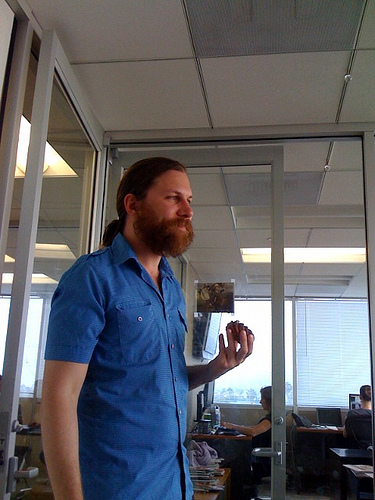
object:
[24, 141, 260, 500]
man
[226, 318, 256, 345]
doughnut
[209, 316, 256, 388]
hand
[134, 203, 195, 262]
bead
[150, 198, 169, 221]
cheeks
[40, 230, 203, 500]
shirt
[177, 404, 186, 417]
buttons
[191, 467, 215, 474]
magazines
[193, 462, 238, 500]
table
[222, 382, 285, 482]
woman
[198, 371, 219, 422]
computer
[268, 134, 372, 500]
screen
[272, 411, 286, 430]
lock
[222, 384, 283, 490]
women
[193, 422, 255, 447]
at desk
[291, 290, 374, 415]
blinds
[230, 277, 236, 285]
taped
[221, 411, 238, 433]
typing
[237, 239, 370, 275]
lights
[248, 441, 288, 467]
handle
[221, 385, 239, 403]
trees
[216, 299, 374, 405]
window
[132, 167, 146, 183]
hair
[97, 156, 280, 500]
newly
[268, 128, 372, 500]
door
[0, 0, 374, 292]
ceiling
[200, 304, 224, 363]
tv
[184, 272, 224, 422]
wall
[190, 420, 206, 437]
pinecone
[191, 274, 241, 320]
image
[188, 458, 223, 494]
pile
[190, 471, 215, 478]
papers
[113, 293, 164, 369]
pocket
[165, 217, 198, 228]
mustache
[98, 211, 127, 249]
ponytail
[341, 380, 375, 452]
office worker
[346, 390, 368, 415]
computer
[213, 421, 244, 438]
keyboard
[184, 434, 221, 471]
items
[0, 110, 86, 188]
lighting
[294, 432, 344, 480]
partition